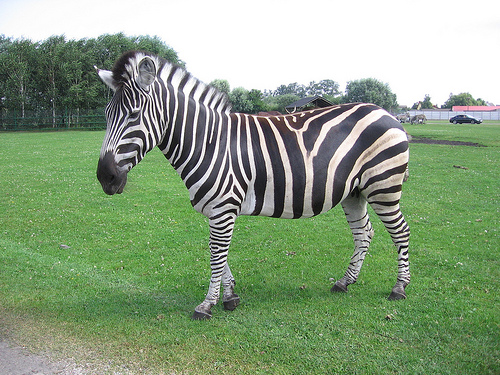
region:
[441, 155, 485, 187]
Possible pile of excriment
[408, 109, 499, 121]
White Wall barricade around structures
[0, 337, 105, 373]
Sandy looking soil area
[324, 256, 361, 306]
A Zebra Hoof on the ground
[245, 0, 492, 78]
oddly bright White sky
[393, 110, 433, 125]
Two Possible sitting elephants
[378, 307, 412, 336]
Debris of some kind on the ground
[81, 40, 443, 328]
A Majestic Looking Zebra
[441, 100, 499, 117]
Red Roof on top of a structure in the background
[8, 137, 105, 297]
Large open grass area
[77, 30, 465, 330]
The zebra is looking to left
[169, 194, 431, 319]
The zebra has four legs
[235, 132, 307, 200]
It has black and white stripes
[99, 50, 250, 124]
The zebra has a medium length mane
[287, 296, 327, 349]
The grass is very short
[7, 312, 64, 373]
beside the grass is a path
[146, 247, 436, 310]
The zebra has four hooves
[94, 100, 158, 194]
The zebra has a black nose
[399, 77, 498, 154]
There is a building in the background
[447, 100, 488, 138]
A car drives down the road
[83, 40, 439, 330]
A Zebra with a Large Head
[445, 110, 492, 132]
A Moving Small Car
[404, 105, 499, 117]
A Structure in the Background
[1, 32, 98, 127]
Trees in the Background.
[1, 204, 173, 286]
Healthy Green Grass on the Ground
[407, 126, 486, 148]
Some sort of Ditch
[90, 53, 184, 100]
The Zebra's Ears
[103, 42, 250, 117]
The Zebra has Mohawk hair.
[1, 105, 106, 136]
Some sort of blue fencing.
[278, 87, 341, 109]
Some sort of roof like structure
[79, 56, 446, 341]
Zebra standing on grass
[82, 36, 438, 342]
Zebra is white with black stripes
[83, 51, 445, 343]
Zebra is black and white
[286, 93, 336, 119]
Black roof of a building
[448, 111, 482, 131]
Black car on the road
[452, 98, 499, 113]
Red roof to building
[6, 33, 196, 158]
Tall trees behind zebra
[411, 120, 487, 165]
Patch of brown dirt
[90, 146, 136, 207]
Black nose of zebra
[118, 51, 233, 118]
Black and white mane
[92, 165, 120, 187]
The nose nostrils of the zebra.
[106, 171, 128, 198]
The mouth area of the zebra.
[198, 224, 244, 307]
The zebra's front left leg.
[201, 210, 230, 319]
The zebra's right left leg.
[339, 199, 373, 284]
The zebra's back left leg.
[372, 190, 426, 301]
The zebra's back right leg.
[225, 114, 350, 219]
The stripes on the zebra's stomach area.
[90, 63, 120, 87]
The zebra's left ear.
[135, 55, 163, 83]
The zebra's right ear.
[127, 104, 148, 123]
The eye of the zebra.